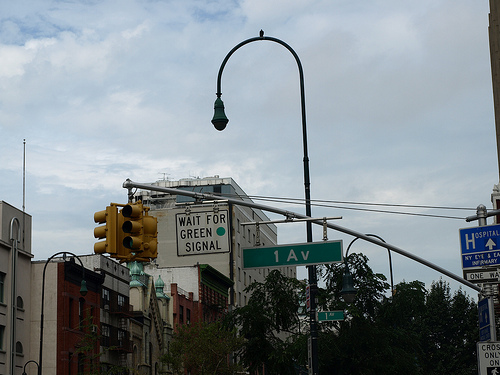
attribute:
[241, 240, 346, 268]
sign — green, white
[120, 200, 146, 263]
light — green, signal, yellow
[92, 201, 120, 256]
light — signal, yellow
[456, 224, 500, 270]
sign — white, blue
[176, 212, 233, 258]
sign — white, black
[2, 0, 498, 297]
sky — blue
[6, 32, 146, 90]
cloud — white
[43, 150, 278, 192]
cloud — white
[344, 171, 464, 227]
cloud — white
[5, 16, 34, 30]
spot — blue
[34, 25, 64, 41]
spot — blue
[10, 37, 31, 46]
spot — blue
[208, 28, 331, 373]
pole — curved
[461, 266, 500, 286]
sign — one way, white, black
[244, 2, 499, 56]
cloud — white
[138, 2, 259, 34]
cloud — white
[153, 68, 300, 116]
cloud — white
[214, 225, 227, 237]
dot — green